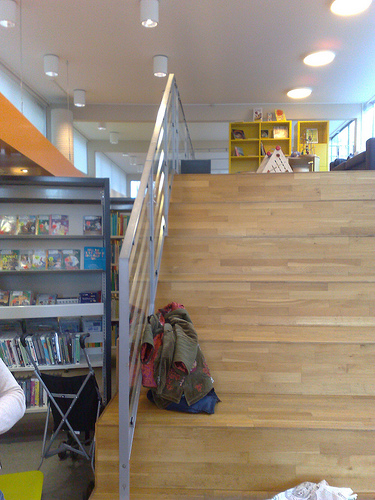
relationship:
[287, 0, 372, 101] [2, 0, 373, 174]
lights on ceiling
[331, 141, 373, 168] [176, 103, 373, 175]
couch sitting on second floor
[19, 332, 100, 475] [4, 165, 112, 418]
stroller in front of a shelf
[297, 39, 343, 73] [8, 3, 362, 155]
light on ceiling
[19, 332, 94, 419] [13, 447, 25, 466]
stroller on ground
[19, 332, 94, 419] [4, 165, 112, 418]
stroller on shelf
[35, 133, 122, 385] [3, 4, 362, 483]
wall on building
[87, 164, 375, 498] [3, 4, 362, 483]
stairs on building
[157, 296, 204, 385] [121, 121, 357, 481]
jacket on stairs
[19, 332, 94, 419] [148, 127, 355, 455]
stroller near stairs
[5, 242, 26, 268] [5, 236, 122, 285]
book on shelf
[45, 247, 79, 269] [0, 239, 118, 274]
book on shelf